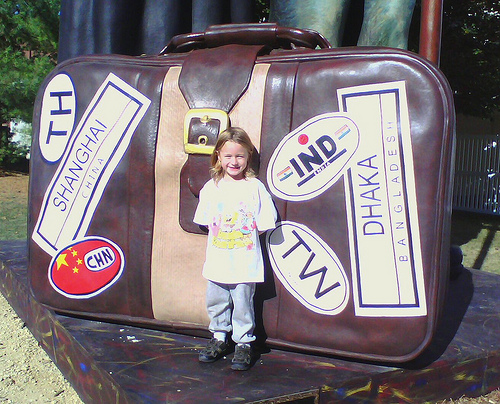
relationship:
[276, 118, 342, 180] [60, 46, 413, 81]
sticker on suitcase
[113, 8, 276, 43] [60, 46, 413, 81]
handle of suitcase